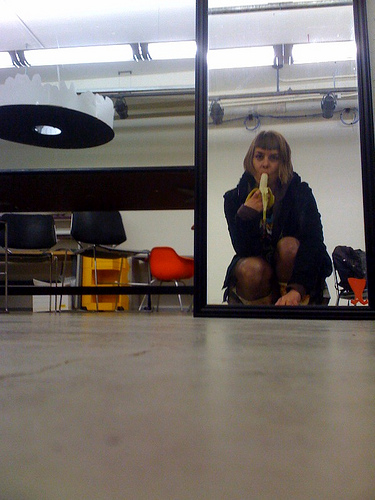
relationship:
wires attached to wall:
[209, 102, 362, 133] [212, 15, 361, 293]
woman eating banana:
[221, 129, 332, 306] [246, 174, 276, 223]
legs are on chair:
[135, 283, 175, 323] [136, 245, 195, 312]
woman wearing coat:
[221, 129, 334, 306] [218, 165, 335, 306]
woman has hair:
[221, 129, 332, 306] [242, 130, 293, 184]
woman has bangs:
[221, 129, 332, 306] [256, 136, 279, 149]